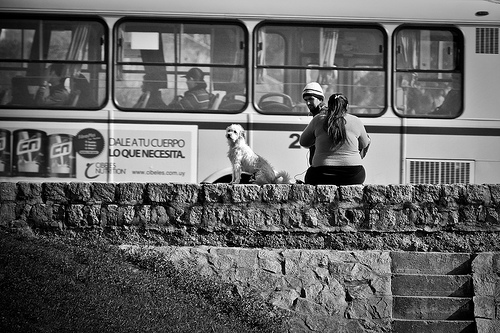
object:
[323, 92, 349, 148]
dark hair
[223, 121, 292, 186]
dog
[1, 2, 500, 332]
scene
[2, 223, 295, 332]
slope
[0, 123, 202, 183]
sign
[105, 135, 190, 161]
spanish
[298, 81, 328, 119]
man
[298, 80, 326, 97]
knit cap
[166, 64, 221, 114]
people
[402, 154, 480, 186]
vent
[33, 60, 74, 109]
man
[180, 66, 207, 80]
cap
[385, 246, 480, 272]
steps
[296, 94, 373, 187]
people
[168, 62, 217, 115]
man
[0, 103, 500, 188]
side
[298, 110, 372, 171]
shirt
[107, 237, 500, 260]
roadway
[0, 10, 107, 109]
windows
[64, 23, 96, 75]
curtain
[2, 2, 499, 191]
bus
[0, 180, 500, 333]
wall